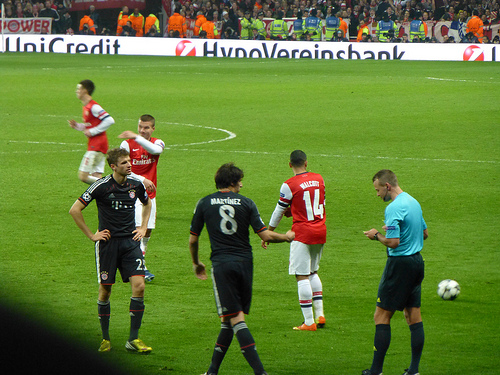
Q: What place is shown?
A: It is a field.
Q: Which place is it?
A: It is a field.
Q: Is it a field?
A: Yes, it is a field.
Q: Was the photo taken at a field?
A: Yes, it was taken in a field.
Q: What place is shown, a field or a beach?
A: It is a field.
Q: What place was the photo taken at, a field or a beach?
A: It was taken at a field.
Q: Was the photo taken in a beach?
A: No, the picture was taken in a field.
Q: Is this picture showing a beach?
A: No, the picture is showing a field.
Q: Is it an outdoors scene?
A: Yes, it is outdoors.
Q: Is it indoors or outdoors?
A: It is outdoors.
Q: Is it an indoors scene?
A: No, it is outdoors.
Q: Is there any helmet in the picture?
A: No, there are no helmets.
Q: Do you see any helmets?
A: No, there are no helmets.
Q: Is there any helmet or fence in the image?
A: No, there are no helmets or fences.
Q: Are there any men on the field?
A: Yes, there is a man on the field.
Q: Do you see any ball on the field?
A: No, there is a man on the field.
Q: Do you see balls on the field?
A: No, there is a man on the field.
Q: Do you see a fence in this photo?
A: No, there are no fences.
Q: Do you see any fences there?
A: No, there are no fences.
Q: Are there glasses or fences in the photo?
A: No, there are no fences or glasses.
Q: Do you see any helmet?
A: No, there are no helmets.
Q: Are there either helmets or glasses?
A: No, there are no helmets or glasses.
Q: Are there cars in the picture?
A: No, there are no cars.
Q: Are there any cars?
A: No, there are no cars.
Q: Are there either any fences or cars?
A: No, there are no cars or fences.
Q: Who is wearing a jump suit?
A: The people are wearing a jump suit.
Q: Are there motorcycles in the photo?
A: No, there are no motorcycles.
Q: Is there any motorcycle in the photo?
A: No, there are no motorcycles.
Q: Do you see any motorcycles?
A: No, there are no motorcycles.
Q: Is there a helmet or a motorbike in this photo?
A: No, there are no motorcycles or helmets.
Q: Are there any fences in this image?
A: No, there are no fences.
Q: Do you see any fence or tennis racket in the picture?
A: No, there are no fences or rackets.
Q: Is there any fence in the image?
A: No, there are no fences.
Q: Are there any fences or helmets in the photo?
A: No, there are no helmets or fences.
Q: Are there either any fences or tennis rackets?
A: No, there are no fences or tennis rackets.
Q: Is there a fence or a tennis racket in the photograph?
A: No, there are no fences or rackets.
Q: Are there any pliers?
A: No, there are no pliers.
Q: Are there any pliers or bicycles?
A: No, there are no pliers or bicycles.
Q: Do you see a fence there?
A: No, there are no fences.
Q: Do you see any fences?
A: No, there are no fences.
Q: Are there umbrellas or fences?
A: No, there are no fences or umbrellas.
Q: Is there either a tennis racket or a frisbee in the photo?
A: No, there are no rackets or frisbees.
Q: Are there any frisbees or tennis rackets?
A: No, there are no tennis rackets or frisbees.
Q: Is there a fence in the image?
A: No, there are no fences.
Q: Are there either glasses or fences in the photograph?
A: No, there are no fences or glasses.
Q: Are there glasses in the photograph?
A: No, there are no glasses.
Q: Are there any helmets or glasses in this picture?
A: No, there are no glasses or helmets.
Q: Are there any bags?
A: No, there are no bags.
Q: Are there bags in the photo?
A: No, there are no bags.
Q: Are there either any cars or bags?
A: No, there are no bags or cars.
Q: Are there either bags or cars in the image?
A: No, there are no bags or cars.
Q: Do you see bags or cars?
A: No, there are no bags or cars.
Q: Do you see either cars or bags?
A: No, there are no bags or cars.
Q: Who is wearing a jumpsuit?
A: The people are wearing a jumpsuit.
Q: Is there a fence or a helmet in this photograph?
A: No, there are no fences or helmets.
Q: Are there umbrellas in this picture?
A: No, there are no umbrellas.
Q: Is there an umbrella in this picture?
A: No, there are no umbrellas.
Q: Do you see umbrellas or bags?
A: No, there are no umbrellas or bags.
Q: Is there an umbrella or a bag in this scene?
A: No, there are no umbrellas or bags.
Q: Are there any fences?
A: No, there are no fences.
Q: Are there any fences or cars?
A: No, there are no fences or cars.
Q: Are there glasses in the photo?
A: No, there are no glasses.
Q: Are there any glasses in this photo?
A: No, there are no glasses.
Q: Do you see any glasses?
A: No, there are no glasses.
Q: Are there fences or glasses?
A: No, there are no glasses or fences.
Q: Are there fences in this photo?
A: No, there are no fences.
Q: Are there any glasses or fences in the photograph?
A: No, there are no fences or glasses.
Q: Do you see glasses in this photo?
A: No, there are no glasses.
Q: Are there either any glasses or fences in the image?
A: No, there are no glasses or fences.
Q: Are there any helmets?
A: No, there are no helmets.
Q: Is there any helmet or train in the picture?
A: No, there are no helmets or trains.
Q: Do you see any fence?
A: No, there are no fences.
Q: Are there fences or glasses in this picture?
A: No, there are no fences or glasses.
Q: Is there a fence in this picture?
A: No, there are no fences.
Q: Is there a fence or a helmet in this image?
A: No, there are no fences or helmets.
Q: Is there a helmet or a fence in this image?
A: No, there are no fences or helmets.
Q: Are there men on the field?
A: Yes, there is a man on the field.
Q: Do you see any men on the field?
A: Yes, there is a man on the field.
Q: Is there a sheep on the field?
A: No, there is a man on the field.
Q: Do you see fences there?
A: No, there are no fences.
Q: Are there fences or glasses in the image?
A: No, there are no fences or glasses.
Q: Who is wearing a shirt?
A: The man is wearing a shirt.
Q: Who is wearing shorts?
A: The man is wearing shorts.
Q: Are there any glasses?
A: No, there are no glasses.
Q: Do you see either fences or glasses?
A: No, there are no glasses or fences.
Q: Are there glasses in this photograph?
A: No, there are no glasses.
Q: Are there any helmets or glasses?
A: No, there are no glasses or helmets.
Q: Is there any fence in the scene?
A: No, there are no fences.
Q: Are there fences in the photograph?
A: No, there are no fences.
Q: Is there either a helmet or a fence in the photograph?
A: No, there are no fences or helmets.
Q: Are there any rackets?
A: No, there are no rackets.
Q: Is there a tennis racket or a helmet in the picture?
A: No, there are no rackets or helmets.